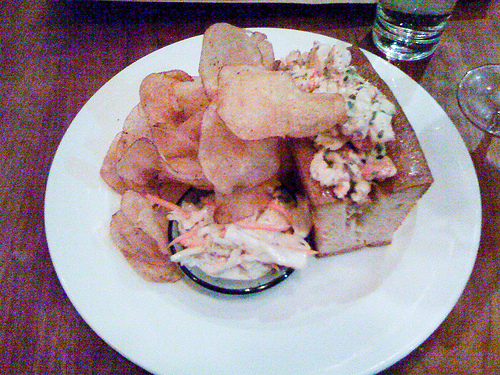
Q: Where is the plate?
A: On table.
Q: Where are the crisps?
A: On plate.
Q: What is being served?
A: Food.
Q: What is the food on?
A: Plate.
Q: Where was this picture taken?
A: Restaurant.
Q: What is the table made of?
A: Wood.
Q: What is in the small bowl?
A: Coleslaw.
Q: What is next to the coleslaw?
A: Chip.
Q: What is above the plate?
A: Glass.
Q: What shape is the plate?
A: Round.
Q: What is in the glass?
A: Water.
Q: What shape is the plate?
A: Round.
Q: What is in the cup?
A: Coleslaw.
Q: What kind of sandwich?
A: Chicken salad.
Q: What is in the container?
A: Coleslaw.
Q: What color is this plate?
A: White.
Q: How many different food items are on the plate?
A: Three.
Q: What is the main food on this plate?
A: A sandwich.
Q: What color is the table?
A: Brown.